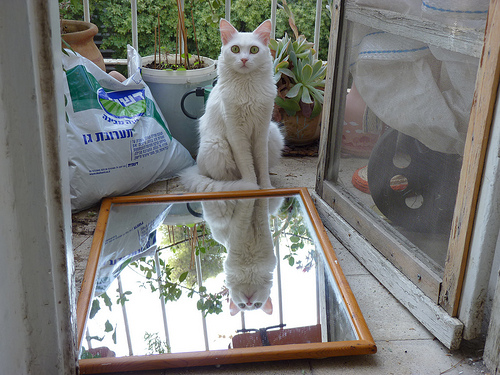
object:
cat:
[175, 17, 287, 191]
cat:
[201, 196, 286, 315]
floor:
[383, 347, 486, 373]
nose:
[240, 58, 249, 65]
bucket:
[138, 53, 220, 160]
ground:
[360, 291, 381, 317]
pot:
[58, 18, 106, 75]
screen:
[323, 0, 494, 269]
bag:
[60, 37, 194, 215]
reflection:
[320, 32, 463, 235]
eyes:
[251, 46, 260, 54]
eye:
[250, 46, 259, 54]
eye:
[231, 45, 240, 53]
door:
[311, 0, 498, 350]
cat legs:
[254, 120, 274, 189]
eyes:
[231, 45, 241, 53]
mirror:
[72, 191, 364, 360]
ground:
[378, 358, 402, 373]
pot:
[274, 91, 322, 145]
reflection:
[84, 194, 317, 325]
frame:
[102, 185, 304, 203]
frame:
[76, 340, 375, 374]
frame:
[299, 187, 377, 339]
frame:
[75, 197, 110, 348]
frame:
[438, 48, 499, 317]